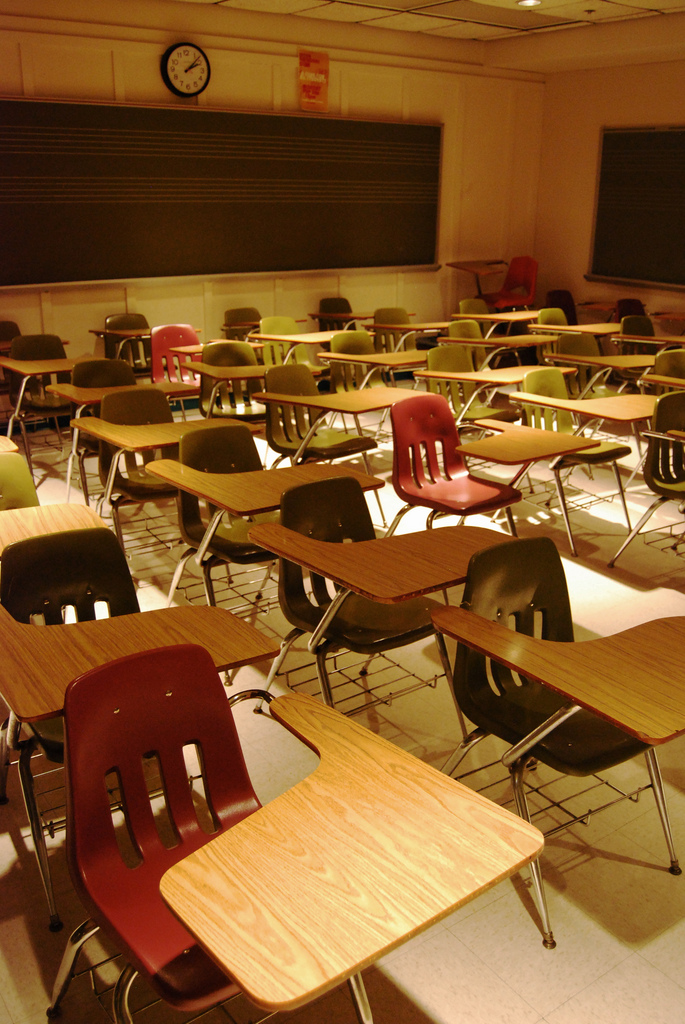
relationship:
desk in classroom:
[240, 518, 511, 747] [47, 38, 631, 780]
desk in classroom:
[139, 441, 386, 625] [19, 23, 660, 679]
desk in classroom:
[61, 410, 268, 565] [19, 23, 660, 679]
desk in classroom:
[249, 382, 445, 528] [19, 23, 660, 679]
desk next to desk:
[453, 401, 579, 487] [518, 355, 642, 540]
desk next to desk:
[249, 384, 437, 412] [411, 528, 682, 844]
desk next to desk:
[256, 314, 347, 363] [356, 294, 448, 398]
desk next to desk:
[37, 360, 155, 419] [241, 302, 343, 416]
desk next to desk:
[510, 367, 640, 470] [253, 466, 475, 722]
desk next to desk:
[90, 386, 225, 468] [253, 464, 480, 684]